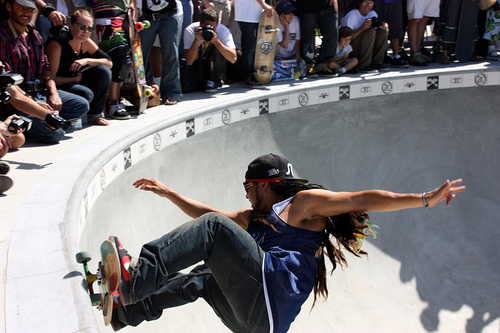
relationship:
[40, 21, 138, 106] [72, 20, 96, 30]
woman wearing sunglasses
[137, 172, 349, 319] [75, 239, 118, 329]
man riding skateboard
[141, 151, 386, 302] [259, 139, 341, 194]
man wearing hat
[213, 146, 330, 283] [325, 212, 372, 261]
man with long hair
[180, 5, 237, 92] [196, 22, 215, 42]
man holding camera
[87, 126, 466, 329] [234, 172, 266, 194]
man wearing glasses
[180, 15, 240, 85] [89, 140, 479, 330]
photographer taking pictures man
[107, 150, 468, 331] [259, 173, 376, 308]
man has long hair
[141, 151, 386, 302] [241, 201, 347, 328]
man wearing jersey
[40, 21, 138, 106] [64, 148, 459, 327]
woman watching skater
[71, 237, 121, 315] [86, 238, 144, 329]
wheel on skateboard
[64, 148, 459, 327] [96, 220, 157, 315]
skater holding skateboard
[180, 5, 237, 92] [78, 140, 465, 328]
man taking pictures skateboarder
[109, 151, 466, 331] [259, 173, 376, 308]
skateboarder has long hair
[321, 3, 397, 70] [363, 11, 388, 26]
man holding camera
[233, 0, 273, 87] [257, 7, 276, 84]
person holds skateboard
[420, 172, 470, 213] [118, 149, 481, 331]
hand of person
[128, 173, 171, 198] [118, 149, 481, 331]
hand of person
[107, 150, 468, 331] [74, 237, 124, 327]
man doing skateboard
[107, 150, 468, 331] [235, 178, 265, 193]
man wearing glasses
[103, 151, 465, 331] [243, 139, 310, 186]
skater wearing a hat